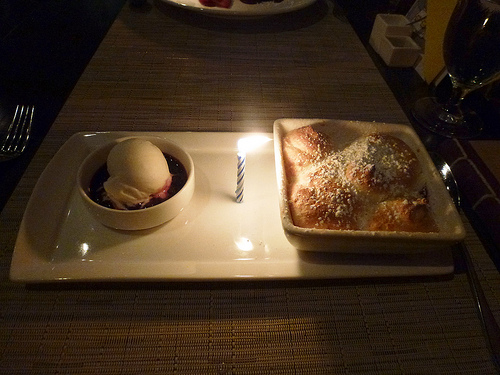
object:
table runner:
[0, 3, 499, 373]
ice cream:
[99, 138, 173, 204]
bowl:
[75, 133, 192, 230]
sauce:
[91, 153, 184, 210]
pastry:
[283, 123, 431, 234]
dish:
[271, 116, 466, 259]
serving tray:
[9, 125, 456, 283]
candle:
[231, 132, 251, 202]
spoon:
[428, 149, 495, 365]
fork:
[1, 106, 33, 164]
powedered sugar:
[301, 130, 431, 224]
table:
[0, 0, 499, 374]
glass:
[410, 3, 495, 141]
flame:
[233, 131, 273, 153]